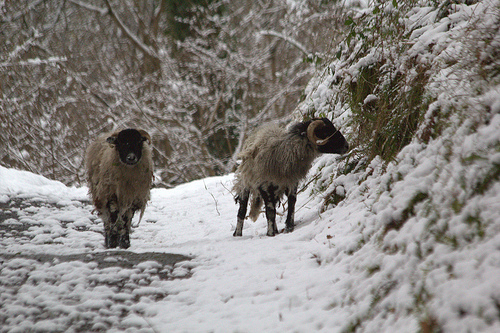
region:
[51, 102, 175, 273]
Black and white sheep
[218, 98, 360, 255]
black and white sheep with horns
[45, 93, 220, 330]
sheep walking on snow covered ground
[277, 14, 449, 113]
green branches covered with white snow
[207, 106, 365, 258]
black and white sheep with snow on its legs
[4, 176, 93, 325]
snow covered path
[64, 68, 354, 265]
two black and white sheep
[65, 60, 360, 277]
two black and white rams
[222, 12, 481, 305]
snow covered hillside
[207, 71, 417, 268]
black and white ram sniffing snow covered hillside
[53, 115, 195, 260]
A horned sheep in the snow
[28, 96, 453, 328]
Two sheep walking in the snow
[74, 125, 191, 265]
Sheep with dirty wool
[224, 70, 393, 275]
Sheep with curved horns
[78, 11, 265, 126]
Icy tree branches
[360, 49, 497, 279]
Snow covered hill side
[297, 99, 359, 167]
Sheep with black face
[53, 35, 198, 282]
The sheep has four legs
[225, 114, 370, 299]
The sheep has snow on its legs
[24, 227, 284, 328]
Snow covered ground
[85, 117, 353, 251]
mountain goats have horns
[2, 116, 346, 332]
mountain goats walking on snowy path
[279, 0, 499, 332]
green plants peek through the snow on the hill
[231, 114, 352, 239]
mountain goat has a black head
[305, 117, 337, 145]
horn is curled and brown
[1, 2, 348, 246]
snow-covered trees behind mountain goats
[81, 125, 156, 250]
mountain goat has a black head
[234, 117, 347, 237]
mountain goat has a shaggy coat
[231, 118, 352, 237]
mountain goat has black legs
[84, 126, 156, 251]
mountain goat has a shaggy coat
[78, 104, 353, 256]
a pair of mountain goats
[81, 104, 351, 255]
two rams that are not is St. Louis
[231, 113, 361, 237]
a ram searches for food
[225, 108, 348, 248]
a ram looking at a snowy hill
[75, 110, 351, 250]
a couple out for a stroll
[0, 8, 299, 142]
snow covered branches in the distance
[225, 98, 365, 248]
a ram looking to its left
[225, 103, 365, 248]
a ram looking to our right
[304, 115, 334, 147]
the horn of a ram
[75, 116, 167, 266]
an animal looking forward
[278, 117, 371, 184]
Horns on ram's head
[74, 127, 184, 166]
Horns on ram's head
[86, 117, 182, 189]
Black fur on head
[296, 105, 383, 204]
Black fur on head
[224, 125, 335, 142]
Shaggy grayish white fur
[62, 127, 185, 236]
Shaggy grayish white fur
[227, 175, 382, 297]
Black legs on ram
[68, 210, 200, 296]
Black legs on ram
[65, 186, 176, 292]
Snow covered ground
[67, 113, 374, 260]
Two rams walking in the snow